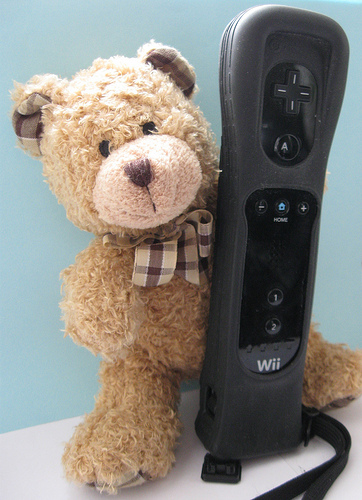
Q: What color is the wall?
A: Blue.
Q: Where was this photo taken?
A: Near a bear and controller.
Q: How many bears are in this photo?
A: One.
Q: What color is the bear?
A: Brown.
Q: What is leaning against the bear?
A: A game controller.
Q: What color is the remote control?
A: Black.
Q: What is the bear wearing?
A: A bow.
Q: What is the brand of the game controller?
A: Wii.